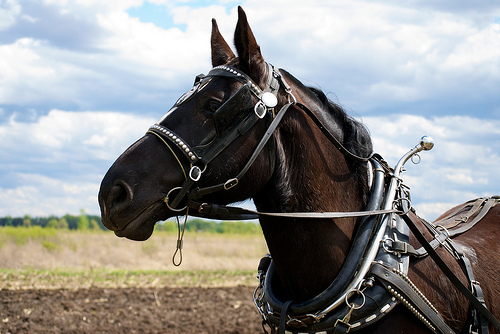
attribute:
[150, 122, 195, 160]
studs — with bridle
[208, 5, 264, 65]
ear — on horse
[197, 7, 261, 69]
ears — dark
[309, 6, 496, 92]
clouds — in the sky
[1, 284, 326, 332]
dirt — with bridle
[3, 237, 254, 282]
field — plowed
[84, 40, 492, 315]
horse — brown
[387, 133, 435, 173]
chrome — on horse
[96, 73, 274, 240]
horse face — dark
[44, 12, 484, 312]
horse — on horse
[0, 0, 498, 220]
sky — blue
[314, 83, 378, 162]
mane — on the horse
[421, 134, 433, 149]
ball — silver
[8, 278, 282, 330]
ground — plowed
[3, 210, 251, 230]
trees — behind horse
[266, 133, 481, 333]
rigging — next to horse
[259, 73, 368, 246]
neck — on horse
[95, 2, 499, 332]
horse — with bridle